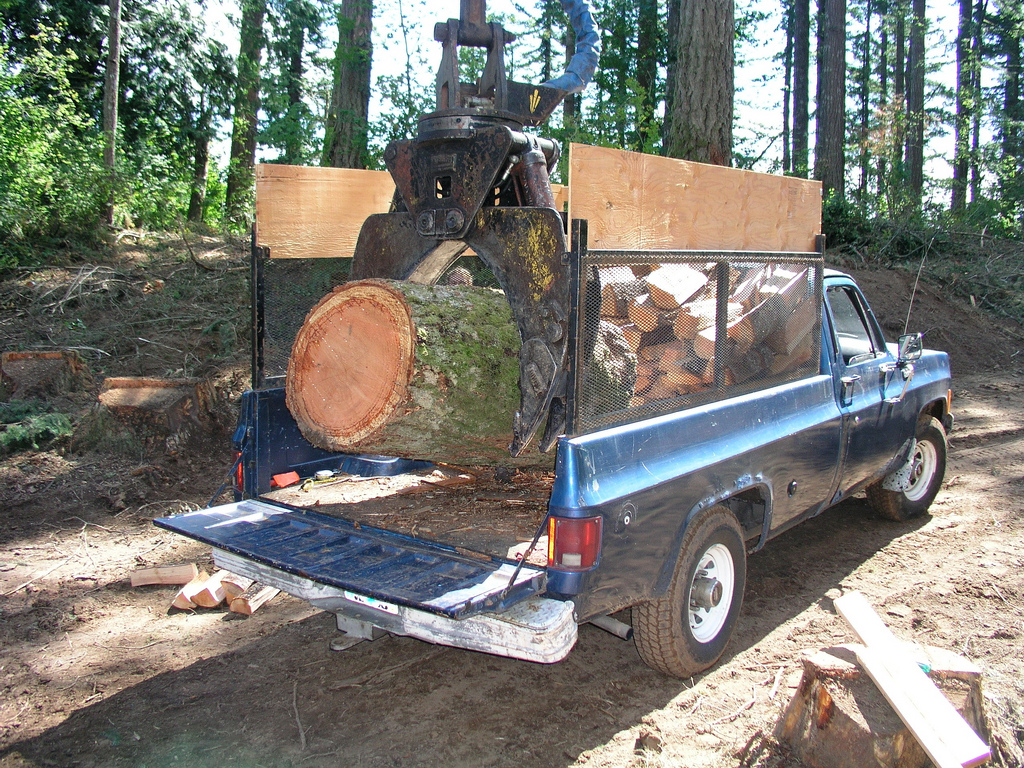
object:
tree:
[807, 0, 861, 235]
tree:
[662, 0, 738, 165]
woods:
[0, 0, 1022, 466]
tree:
[942, 0, 985, 216]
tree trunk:
[285, 278, 528, 468]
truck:
[151, 144, 954, 675]